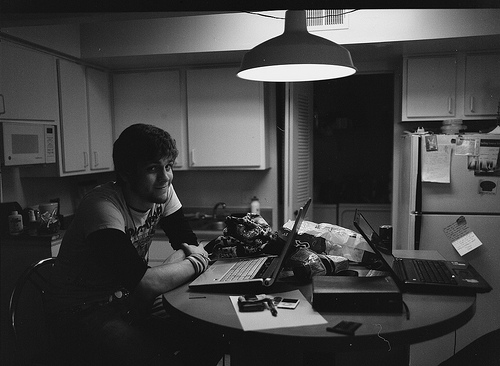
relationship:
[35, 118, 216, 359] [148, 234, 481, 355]
man sitting at table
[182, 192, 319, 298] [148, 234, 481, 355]
computer on table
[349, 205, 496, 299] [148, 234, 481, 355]
computer on table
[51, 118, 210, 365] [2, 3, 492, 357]
man in kitchen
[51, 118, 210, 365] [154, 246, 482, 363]
man sitting at table